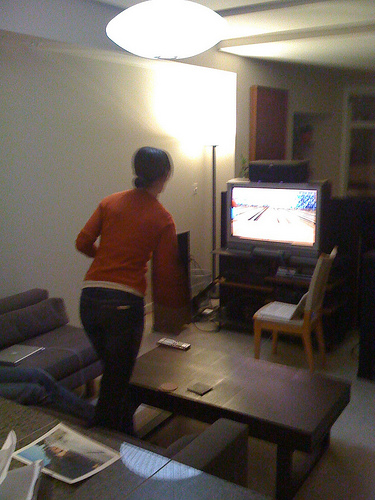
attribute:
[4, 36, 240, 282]
wall — part, white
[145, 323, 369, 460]
table — edge, wooden, part, coffee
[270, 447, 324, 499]
stand — entertainment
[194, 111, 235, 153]
shade — part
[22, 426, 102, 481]
picture — edge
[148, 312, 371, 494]
floor — part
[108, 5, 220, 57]
light — on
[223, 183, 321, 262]
television — on, silver, framed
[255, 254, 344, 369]
chair — brown, wooden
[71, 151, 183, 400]
lady — standing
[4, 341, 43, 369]
laptop — off, silver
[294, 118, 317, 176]
someone — standing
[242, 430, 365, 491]
legs — folded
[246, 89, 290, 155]
chart — part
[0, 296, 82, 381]
sofa — grey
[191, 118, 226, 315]
floor lamp — lit up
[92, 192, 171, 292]
shirt — orange, long sleeved